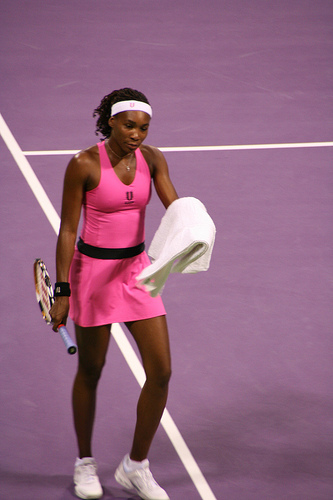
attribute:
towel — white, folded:
[136, 196, 218, 298]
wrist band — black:
[54, 281, 72, 297]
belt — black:
[77, 236, 146, 259]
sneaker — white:
[73, 455, 104, 499]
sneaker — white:
[114, 452, 171, 499]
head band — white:
[111, 99, 153, 117]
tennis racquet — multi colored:
[33, 258, 78, 356]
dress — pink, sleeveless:
[69, 141, 168, 328]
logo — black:
[125, 191, 136, 205]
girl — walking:
[48, 87, 180, 499]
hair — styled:
[93, 87, 150, 140]